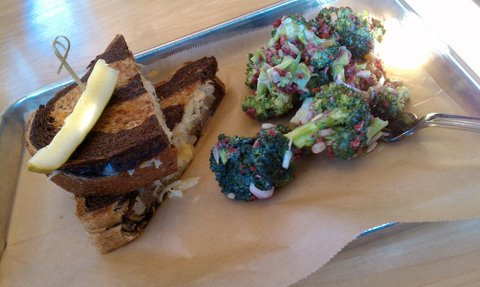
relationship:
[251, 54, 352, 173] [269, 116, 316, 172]
broccoli by onions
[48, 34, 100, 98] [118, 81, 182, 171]
toothpick in bread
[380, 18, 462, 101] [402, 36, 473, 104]
cream has colors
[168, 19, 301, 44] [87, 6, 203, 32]
tray on table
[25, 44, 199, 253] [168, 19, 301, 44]
sandwich on tray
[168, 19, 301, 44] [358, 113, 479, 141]
tray with fork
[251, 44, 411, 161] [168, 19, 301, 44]
salad on tray